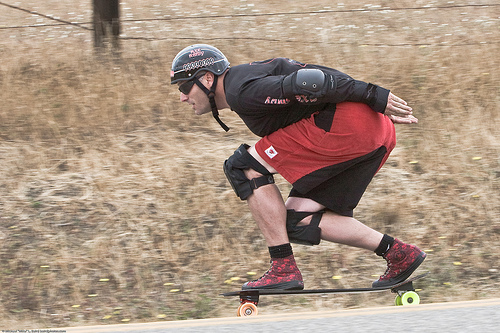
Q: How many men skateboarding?
A: One.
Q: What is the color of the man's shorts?
A: Red and black.